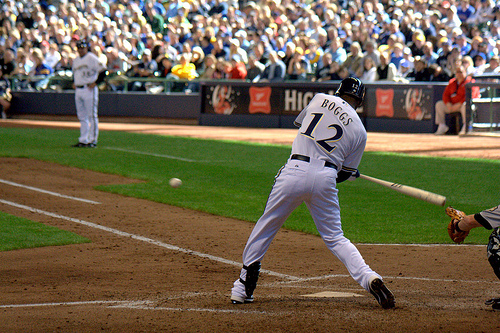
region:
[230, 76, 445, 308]
the baseball player swinging a bat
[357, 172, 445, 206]
the wooden baseball bat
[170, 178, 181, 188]
the baseball in motion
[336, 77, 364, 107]
the helmet on the head of the baseball player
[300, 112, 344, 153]
the number 12 on the back of the shirt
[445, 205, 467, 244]
the catcher's mitt behind the bat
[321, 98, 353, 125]
the name "BOGGS" on the shirt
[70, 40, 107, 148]
the baseball player standing on the grass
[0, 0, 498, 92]
the people sitting in the audience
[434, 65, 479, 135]
the man sitting and wearing a red jacket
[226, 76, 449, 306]
Boggs getting ready to swing at the ball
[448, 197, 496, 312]
Catcher crouching behind the batter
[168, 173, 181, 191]
Baseball making its way to the batter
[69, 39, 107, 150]
First base coach watching the action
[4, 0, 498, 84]
Fans in the stands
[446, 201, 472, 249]
Glove on the catcher's left hand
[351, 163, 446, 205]
Wooden baseball bat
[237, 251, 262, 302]
Protective padding on batter's left ankle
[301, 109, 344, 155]
The number 12 on batter's jersey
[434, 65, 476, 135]
Man in red jacket seated by fence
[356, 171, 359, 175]
Hand on the bat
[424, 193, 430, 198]
A bat swinging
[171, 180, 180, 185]
A ball flying in the air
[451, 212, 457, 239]
Hands in gloves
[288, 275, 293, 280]
A white line on the ground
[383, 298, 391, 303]
Exposed studs on the shoe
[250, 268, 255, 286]
Shin protector turned to the side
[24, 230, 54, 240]
Grass on the ground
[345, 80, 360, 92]
A hard hat on the head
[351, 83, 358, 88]
Number on the hat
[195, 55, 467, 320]
A baseball player swinging a bat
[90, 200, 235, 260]
A dirt baseball field surface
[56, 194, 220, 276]
White lines painted on a baseball field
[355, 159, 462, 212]
A brown wooden baseball bat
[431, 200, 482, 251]
A brown catcher's mitt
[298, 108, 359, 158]
The number 12 on a baseball jersey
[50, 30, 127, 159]
A man wearing white baseball pants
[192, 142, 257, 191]
A green grass surface of a baseball field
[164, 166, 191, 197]
A white baseball flying through the air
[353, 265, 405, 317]
A man's baseball shoe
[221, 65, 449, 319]
batter holding a bat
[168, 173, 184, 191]
baseball flying through the air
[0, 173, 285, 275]
white lines on the dirt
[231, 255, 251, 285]
two black straps around the leg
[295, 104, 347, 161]
black number on the back of the jersey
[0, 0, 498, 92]
spectators in the stands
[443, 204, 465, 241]
light brown catcher's mit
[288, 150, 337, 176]
black belt holding up the pants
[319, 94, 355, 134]
name on the back of the jersey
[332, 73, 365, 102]
helmet on the head